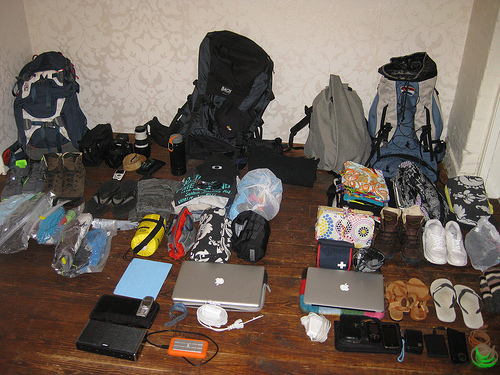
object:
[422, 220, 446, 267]
tennis shoe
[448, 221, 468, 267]
tennis shoe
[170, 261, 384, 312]
two laptops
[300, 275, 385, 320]
striped knit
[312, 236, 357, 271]
kit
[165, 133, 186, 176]
bottle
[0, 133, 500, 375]
table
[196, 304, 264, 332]
adaptors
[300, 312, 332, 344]
adaptors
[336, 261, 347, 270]
cross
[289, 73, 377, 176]
backpack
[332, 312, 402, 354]
electronic devices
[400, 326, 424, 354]
electronic devices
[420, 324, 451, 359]
electronic devices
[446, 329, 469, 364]
electronic devices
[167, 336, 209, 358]
cell phone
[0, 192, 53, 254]
bags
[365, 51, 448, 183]
backpack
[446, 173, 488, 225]
towels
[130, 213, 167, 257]
travel pack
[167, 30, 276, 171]
backpack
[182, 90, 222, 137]
pocket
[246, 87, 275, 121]
pocket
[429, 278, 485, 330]
flip flops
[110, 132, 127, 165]
camera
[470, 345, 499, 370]
green band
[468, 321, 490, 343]
red band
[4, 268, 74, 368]
floor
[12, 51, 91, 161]
back pack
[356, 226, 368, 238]
sign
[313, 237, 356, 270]
case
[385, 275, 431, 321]
sandals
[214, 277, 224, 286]
apple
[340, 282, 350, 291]
apple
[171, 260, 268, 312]
computer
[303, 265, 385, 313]
computer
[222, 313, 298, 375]
floor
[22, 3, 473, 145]
wall